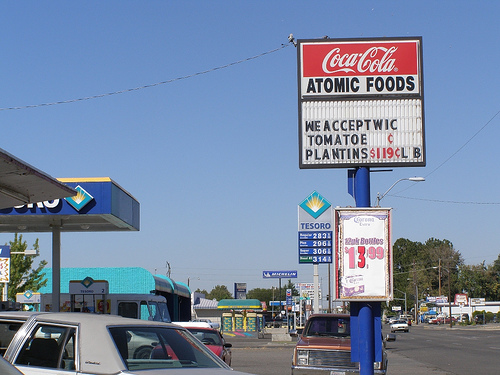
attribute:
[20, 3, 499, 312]
sky — blue 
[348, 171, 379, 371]
pole — blue 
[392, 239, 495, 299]
leaves — green 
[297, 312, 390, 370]
car — brown 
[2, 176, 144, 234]
awning — blue 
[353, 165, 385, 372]
post — blue 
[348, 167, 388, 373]
post — blue 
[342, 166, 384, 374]
post — blue 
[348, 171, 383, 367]
post — blue 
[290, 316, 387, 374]
car — brown 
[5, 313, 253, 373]
car — silver 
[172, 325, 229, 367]
car — red 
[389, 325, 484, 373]
road — asphalt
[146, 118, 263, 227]
sky — clear, blue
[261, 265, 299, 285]
sign — tall, michelin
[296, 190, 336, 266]
sign — a tesoro gas station price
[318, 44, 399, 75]
logo — white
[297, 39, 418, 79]
rectangle — red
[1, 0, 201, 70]
sky — blue, daytime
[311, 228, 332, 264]
numbers — rows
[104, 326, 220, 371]
window — back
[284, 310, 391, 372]
truck — brown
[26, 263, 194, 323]
building — green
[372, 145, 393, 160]
numbers — red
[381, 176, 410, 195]
pole — curved